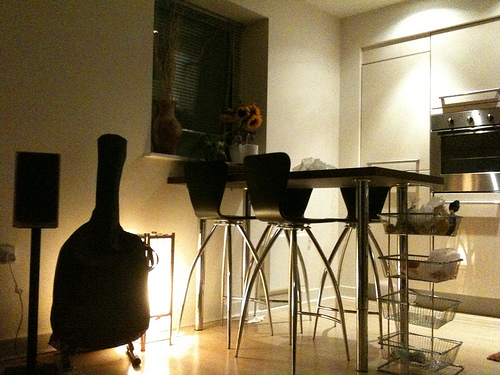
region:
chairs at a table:
[179, 109, 421, 346]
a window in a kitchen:
[123, 62, 293, 174]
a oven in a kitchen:
[420, 97, 490, 183]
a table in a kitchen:
[185, 141, 460, 231]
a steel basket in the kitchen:
[371, 181, 486, 336]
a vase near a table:
[140, 82, 200, 168]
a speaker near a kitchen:
[7, 149, 79, 258]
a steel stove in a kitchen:
[397, 83, 494, 204]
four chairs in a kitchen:
[170, 134, 444, 307]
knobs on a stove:
[434, 107, 497, 132]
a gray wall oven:
[427, 109, 499, 196]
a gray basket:
[384, 285, 459, 327]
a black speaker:
[10, 148, 67, 237]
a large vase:
[152, 89, 187, 153]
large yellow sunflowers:
[217, 100, 264, 145]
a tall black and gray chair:
[234, 150, 352, 371]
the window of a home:
[153, 0, 243, 136]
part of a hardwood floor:
[1, 290, 498, 374]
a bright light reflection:
[144, 270, 194, 342]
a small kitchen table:
[165, 146, 444, 363]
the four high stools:
[166, 137, 273, 349]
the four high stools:
[177, 115, 396, 371]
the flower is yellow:
[212, 90, 279, 160]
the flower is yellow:
[187, 68, 285, 180]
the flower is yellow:
[209, 87, 344, 254]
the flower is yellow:
[230, 100, 300, 200]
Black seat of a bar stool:
[235, 151, 329, 238]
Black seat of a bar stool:
[175, 150, 250, 239]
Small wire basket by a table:
[383, 198, 463, 246]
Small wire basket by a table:
[371, 241, 458, 288]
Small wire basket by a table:
[371, 279, 467, 329]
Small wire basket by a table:
[365, 324, 477, 374]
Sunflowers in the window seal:
[206, 85, 265, 172]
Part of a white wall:
[28, 26, 81, 63]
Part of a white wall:
[40, 98, 82, 142]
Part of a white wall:
[288, 76, 348, 128]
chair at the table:
[171, 158, 272, 374]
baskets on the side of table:
[369, 203, 472, 373]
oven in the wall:
[417, 99, 498, 182]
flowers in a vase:
[231, 103, 283, 159]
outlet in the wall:
[3, 236, 49, 349]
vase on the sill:
[163, 93, 197, 167]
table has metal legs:
[319, 144, 445, 373]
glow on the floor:
[103, 224, 208, 374]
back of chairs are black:
[249, 154, 317, 245]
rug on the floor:
[484, 334, 498, 374]